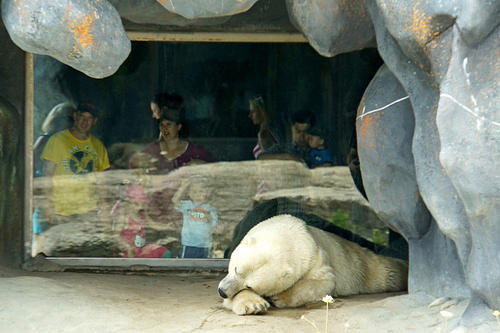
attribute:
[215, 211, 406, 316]
polar bear — white, sleeping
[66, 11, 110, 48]
spots — orange, beautiful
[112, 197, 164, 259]
dress — short, red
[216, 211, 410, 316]
bear — polar bear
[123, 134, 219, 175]
shirt — purple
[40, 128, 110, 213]
shirt — yellow, decorated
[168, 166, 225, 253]
shirt — white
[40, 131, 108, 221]
shirt — yellow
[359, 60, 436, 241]
rock — big, grey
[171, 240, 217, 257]
pant — stripped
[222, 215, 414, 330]
bear — asleep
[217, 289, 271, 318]
claws — sharp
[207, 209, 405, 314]
bear — white, big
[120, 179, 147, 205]
cap — beautiful pink 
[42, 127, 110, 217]
t-shirt — yellow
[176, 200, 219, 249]
baby tee — white